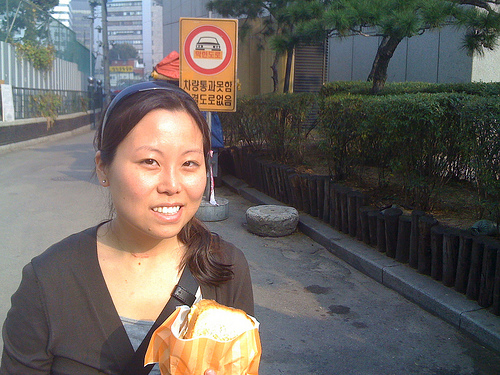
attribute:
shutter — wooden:
[298, 34, 330, 89]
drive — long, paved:
[0, 129, 496, 374]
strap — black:
[163, 267, 195, 297]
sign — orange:
[178, 15, 239, 113]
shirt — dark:
[39, 250, 90, 320]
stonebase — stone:
[246, 192, 306, 240]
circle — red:
[186, 27, 231, 75]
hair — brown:
[103, 88, 232, 295]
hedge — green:
[228, 93, 497, 185]